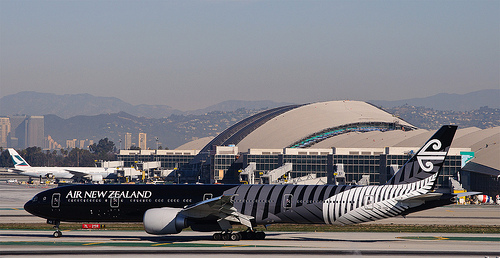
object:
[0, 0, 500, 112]
sky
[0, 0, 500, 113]
cloud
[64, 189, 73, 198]
letters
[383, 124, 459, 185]
tail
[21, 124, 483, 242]
airplane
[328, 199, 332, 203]
window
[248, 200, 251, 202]
window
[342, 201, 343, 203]
window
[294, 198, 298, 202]
window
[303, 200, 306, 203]
window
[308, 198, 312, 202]
window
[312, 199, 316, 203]
window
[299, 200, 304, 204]
window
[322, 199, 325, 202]
window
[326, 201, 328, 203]
window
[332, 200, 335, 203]
window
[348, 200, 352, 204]
window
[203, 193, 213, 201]
windows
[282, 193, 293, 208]
windows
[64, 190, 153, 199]
logo